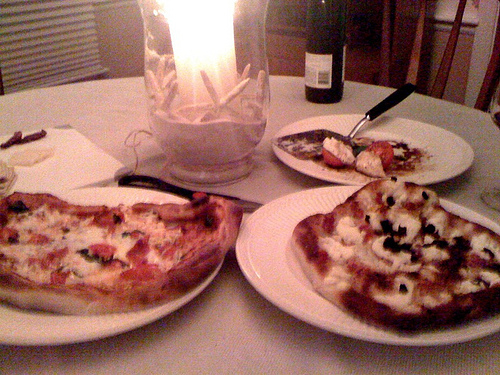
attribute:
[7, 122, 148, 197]
plate — white 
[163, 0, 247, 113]
candle — white 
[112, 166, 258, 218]
scissors — pair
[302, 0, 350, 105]
bottle — black , dark , glass 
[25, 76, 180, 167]
table cloth — white 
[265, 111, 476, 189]
plate — white 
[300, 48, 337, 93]
sticker — white 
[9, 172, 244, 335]
pizza — cut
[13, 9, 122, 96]
blinds — white 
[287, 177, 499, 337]
pizza — small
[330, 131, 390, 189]
tomato — red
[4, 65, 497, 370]
table — covered 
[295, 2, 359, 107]
bottle — brown 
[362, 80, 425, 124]
handle — black